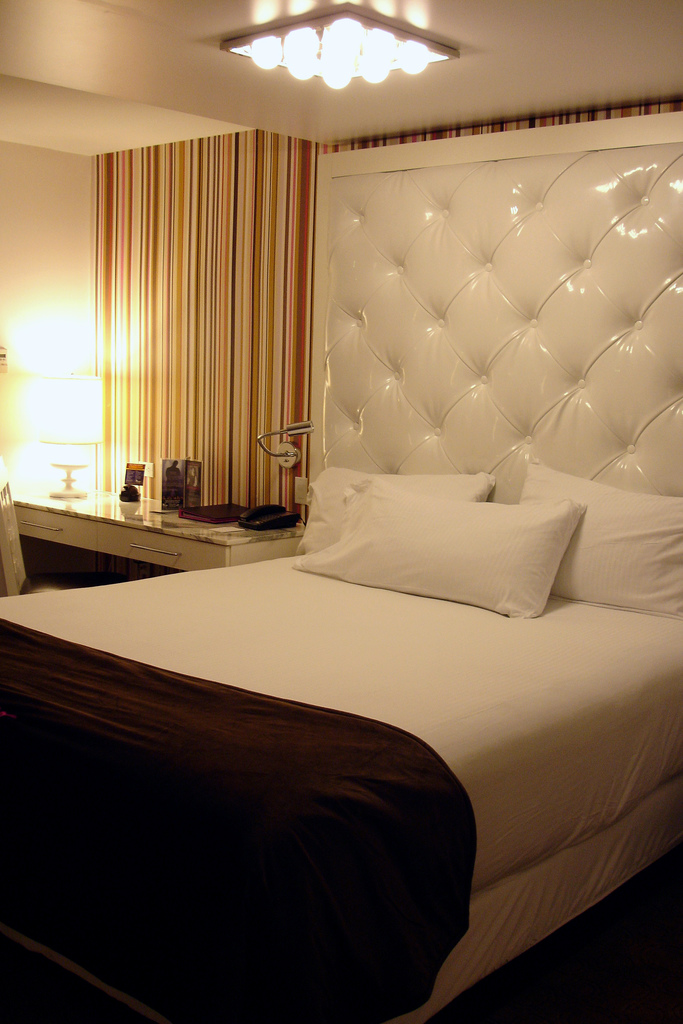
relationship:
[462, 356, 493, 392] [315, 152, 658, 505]
button on board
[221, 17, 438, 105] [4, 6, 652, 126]
lightbulbs are on ceiling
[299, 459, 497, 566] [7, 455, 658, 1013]
pillow are on bed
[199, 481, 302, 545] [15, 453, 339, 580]
phone on table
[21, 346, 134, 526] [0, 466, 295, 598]
lamp on table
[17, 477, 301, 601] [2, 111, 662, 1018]
desk standing next to bed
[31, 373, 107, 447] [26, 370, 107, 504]
shade covering table lamp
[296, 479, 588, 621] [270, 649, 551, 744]
pillow on bed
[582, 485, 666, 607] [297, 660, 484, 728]
pillow on bed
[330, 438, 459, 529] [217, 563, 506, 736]
pillow on bed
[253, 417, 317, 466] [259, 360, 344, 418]
lamp attached wall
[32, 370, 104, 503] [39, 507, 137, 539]
lamp on desk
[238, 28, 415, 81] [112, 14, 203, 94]
light on ceiling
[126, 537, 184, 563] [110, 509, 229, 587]
handle attached to drawer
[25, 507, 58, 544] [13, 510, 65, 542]
handle attached to drawer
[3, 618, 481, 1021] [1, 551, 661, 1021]
blanket lying on top of bed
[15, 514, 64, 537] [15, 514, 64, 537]
drawer handles mounted on drawer handles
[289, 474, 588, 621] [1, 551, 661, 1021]
pillow lying on top of bed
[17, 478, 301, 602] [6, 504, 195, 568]
desk with drawer handles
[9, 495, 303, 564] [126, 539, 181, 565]
drawer has handle